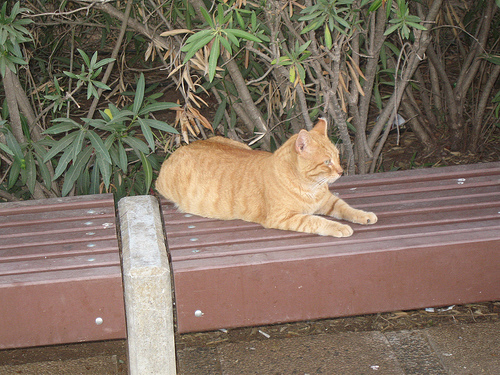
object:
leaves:
[175, 7, 275, 81]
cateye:
[323, 158, 331, 165]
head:
[273, 117, 344, 191]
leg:
[320, 195, 378, 225]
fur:
[192, 170, 289, 194]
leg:
[300, 212, 353, 238]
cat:
[155, 118, 379, 239]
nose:
[337, 169, 344, 176]